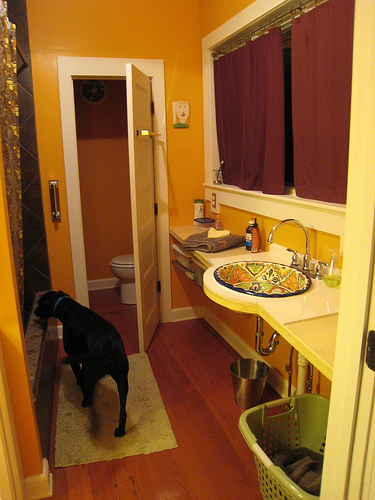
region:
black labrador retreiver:
[33, 284, 144, 438]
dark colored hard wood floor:
[174, 383, 238, 496]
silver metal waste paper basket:
[216, 353, 284, 407]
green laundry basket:
[234, 394, 319, 498]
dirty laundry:
[270, 446, 327, 491]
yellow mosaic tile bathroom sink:
[213, 259, 315, 302]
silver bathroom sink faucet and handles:
[260, 211, 316, 281]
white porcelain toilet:
[103, 239, 138, 316]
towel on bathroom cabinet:
[181, 224, 240, 255]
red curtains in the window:
[209, 80, 342, 164]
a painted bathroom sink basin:
[213, 251, 307, 301]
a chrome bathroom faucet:
[267, 215, 327, 276]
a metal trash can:
[230, 358, 268, 409]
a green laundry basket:
[239, 389, 327, 498]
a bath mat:
[54, 345, 177, 466]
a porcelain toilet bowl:
[108, 248, 136, 302]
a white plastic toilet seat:
[108, 254, 134, 269]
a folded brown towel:
[179, 228, 243, 253]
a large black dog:
[28, 284, 133, 441]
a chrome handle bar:
[47, 179, 62, 224]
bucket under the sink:
[223, 342, 283, 396]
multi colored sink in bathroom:
[211, 250, 309, 303]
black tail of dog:
[87, 347, 152, 395]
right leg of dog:
[100, 393, 150, 449]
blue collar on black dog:
[47, 296, 74, 313]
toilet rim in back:
[99, 249, 129, 274]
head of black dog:
[24, 285, 69, 333]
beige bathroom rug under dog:
[78, 335, 166, 497]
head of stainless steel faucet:
[260, 225, 298, 265]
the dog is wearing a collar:
[51, 288, 71, 316]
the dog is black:
[27, 274, 147, 456]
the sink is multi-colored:
[217, 261, 303, 294]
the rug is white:
[139, 378, 159, 439]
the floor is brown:
[181, 374, 208, 454]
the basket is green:
[238, 409, 279, 495]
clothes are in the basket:
[279, 443, 317, 485]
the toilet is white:
[106, 251, 134, 306]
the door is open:
[134, 267, 163, 350]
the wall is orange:
[7, 362, 32, 440]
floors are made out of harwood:
[195, 464, 229, 494]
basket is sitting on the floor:
[248, 436, 291, 496]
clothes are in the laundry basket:
[291, 451, 314, 497]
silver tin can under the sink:
[224, 358, 262, 403]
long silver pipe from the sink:
[256, 330, 260, 345]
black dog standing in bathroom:
[49, 297, 123, 421]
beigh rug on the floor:
[130, 432, 156, 445]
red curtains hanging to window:
[222, 63, 256, 132]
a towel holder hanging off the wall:
[53, 176, 62, 213]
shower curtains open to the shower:
[5, 30, 10, 143]